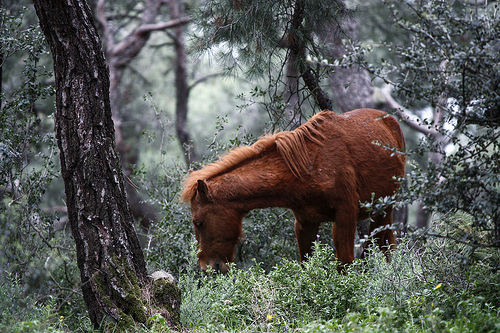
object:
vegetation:
[141, 192, 498, 331]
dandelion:
[12, 300, 78, 332]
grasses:
[0, 250, 500, 333]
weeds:
[416, 272, 466, 315]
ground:
[433, 148, 458, 186]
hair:
[183, 112, 328, 202]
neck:
[211, 150, 295, 218]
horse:
[178, 108, 407, 276]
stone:
[145, 269, 183, 330]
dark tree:
[29, 3, 186, 331]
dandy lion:
[433, 282, 443, 292]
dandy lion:
[266, 314, 272, 320]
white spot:
[100, 187, 106, 204]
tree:
[354, 0, 499, 266]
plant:
[204, 246, 389, 328]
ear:
[197, 179, 209, 203]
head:
[181, 167, 242, 275]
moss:
[96, 269, 154, 331]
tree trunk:
[30, 1, 177, 333]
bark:
[37, 5, 184, 333]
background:
[4, 0, 499, 331]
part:
[348, 255, 377, 275]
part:
[188, 199, 208, 244]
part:
[186, 212, 206, 248]